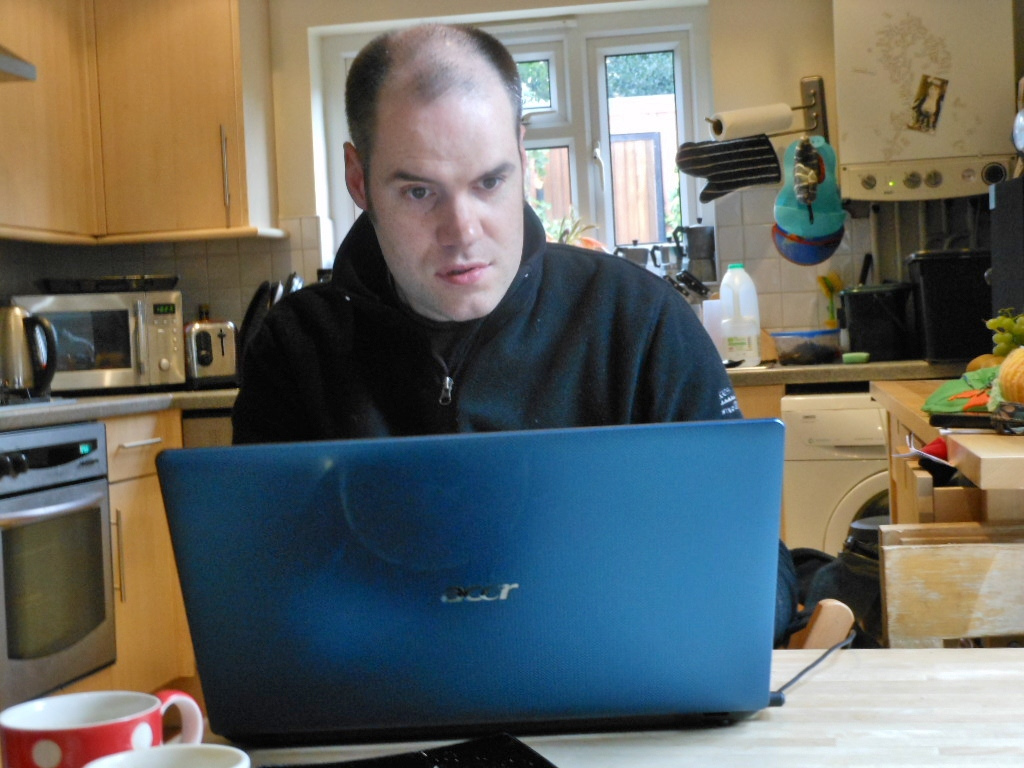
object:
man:
[232, 21, 798, 649]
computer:
[153, 417, 785, 752]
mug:
[0, 690, 205, 768]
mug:
[80, 742, 250, 768]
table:
[165, 647, 1024, 768]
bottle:
[719, 263, 762, 367]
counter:
[726, 360, 968, 387]